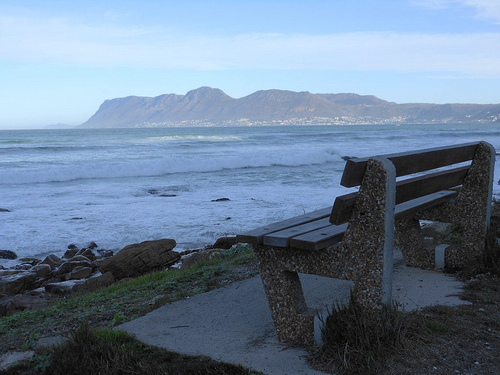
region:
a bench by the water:
[15, 66, 485, 317]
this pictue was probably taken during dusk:
[19, 32, 483, 243]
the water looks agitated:
[9, 128, 371, 197]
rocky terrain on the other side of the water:
[72, 86, 483, 121]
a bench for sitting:
[244, 148, 492, 313]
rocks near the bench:
[5, 238, 175, 317]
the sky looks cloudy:
[13, 9, 480, 111]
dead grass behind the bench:
[320, 271, 498, 370]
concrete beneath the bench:
[108, 275, 457, 371]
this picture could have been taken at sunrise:
[6, 113, 495, 334]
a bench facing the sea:
[234, 122, 481, 344]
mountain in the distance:
[88, 82, 193, 132]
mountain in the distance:
[187, 69, 333, 139]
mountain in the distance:
[313, 80, 485, 142]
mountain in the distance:
[160, 77, 258, 155]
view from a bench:
[83, 33, 487, 364]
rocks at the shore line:
[35, 237, 185, 282]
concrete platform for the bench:
[140, 286, 355, 361]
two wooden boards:
[405, 150, 460, 190]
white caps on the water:
[150, 130, 245, 145]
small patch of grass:
[105, 265, 172, 295]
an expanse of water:
[25, 132, 260, 173]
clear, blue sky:
[10, 41, 162, 86]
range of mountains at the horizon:
[76, 80, 308, 112]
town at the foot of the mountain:
[141, 111, 271, 129]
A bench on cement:
[142, 132, 499, 373]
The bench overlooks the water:
[86, 78, 498, 373]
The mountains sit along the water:
[81, 82, 494, 131]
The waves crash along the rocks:
[66, 145, 336, 184]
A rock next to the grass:
[99, 236, 199, 284]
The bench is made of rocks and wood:
[233, 132, 498, 356]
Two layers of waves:
[144, 128, 296, 174]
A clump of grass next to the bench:
[324, 293, 424, 368]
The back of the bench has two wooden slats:
[331, 138, 492, 228]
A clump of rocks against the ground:
[3, 238, 185, 294]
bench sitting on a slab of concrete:
[205, 133, 493, 353]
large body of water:
[4, 127, 496, 285]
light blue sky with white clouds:
[0, 3, 497, 130]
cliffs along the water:
[77, 85, 499, 134]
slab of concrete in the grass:
[104, 221, 497, 374]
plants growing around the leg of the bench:
[312, 289, 412, 371]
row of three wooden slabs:
[223, 158, 464, 266]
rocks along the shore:
[0, 227, 175, 307]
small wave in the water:
[132, 131, 243, 144]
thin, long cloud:
[15, 13, 497, 80]